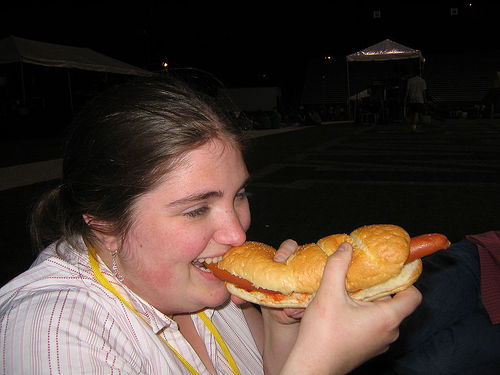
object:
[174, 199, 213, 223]
eye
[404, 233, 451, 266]
dog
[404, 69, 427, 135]
man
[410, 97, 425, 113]
shorts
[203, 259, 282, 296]
long hotdog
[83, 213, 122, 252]
earring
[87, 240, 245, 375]
lanyard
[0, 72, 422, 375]
girl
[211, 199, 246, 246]
nose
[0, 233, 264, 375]
shirts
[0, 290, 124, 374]
stripes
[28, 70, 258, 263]
hair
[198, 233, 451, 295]
hot dog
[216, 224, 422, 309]
bun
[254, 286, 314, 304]
ketchup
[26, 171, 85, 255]
pony tail